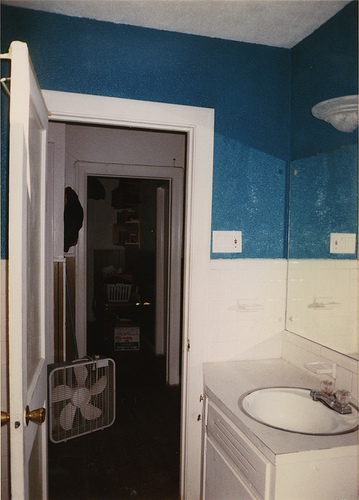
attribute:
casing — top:
[77, 147, 172, 190]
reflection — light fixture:
[308, 82, 348, 124]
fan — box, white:
[6, 344, 130, 436]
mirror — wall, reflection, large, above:
[243, 192, 349, 360]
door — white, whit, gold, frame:
[6, 104, 69, 371]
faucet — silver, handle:
[298, 371, 346, 429]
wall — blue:
[167, 169, 287, 323]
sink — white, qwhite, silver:
[244, 370, 331, 455]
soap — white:
[282, 330, 336, 396]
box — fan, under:
[21, 320, 149, 476]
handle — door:
[9, 403, 56, 436]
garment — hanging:
[48, 162, 98, 254]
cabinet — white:
[188, 399, 272, 497]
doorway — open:
[41, 136, 212, 440]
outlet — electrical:
[200, 225, 262, 283]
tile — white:
[228, 264, 265, 314]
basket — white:
[100, 300, 156, 355]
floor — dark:
[122, 425, 155, 494]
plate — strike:
[220, 340, 318, 423]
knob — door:
[13, 391, 54, 431]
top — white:
[207, 352, 306, 464]